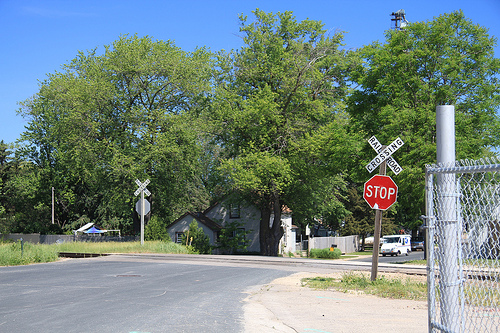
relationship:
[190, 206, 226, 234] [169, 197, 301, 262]
roof on house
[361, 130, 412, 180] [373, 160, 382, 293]
sign on pole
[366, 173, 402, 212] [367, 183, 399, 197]
stop sign has letters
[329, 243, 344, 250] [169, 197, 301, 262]
mailbox in front of house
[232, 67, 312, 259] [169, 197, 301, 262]
tree beside house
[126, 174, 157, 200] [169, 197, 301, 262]
crossing sign by house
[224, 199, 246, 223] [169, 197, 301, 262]
windows on house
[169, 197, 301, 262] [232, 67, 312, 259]
house behind tree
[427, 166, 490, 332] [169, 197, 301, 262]
fence front of house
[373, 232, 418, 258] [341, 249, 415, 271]
truck on road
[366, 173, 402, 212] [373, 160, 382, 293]
stop sign attached to pole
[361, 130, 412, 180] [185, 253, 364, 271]
crossing sign by road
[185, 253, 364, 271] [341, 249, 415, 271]
road over road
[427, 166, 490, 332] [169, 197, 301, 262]
fence next  to house